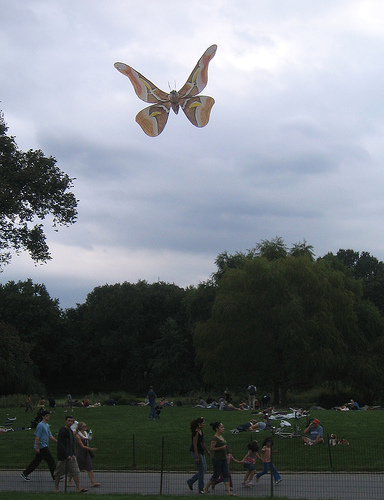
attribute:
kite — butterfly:
[113, 42, 216, 137]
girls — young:
[227, 440, 283, 489]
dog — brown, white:
[326, 433, 351, 448]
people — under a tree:
[246, 381, 259, 413]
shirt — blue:
[33, 420, 53, 449]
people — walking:
[201, 420, 237, 500]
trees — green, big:
[0, 241, 383, 397]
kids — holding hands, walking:
[240, 441, 259, 488]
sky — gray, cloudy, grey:
[78, 138, 383, 246]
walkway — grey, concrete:
[0, 471, 381, 500]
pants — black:
[21, 449, 56, 482]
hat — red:
[312, 418, 319, 426]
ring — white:
[78, 431, 90, 442]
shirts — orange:
[260, 446, 272, 464]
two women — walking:
[187, 418, 210, 496]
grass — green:
[96, 414, 190, 470]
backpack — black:
[247, 386, 257, 397]